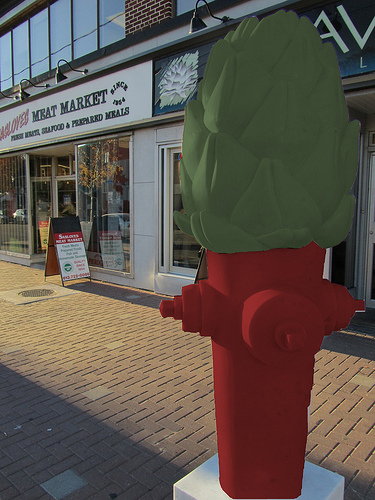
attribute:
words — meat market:
[31, 86, 108, 124]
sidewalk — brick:
[0, 259, 374, 499]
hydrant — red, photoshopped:
[157, 6, 365, 500]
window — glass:
[157, 142, 204, 279]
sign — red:
[42, 213, 93, 290]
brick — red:
[124, 0, 177, 38]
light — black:
[53, 59, 91, 83]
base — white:
[171, 450, 346, 499]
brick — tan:
[327, 430, 361, 448]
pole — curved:
[57, 58, 84, 73]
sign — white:
[0, 60, 155, 155]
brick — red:
[157, 8, 180, 18]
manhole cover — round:
[18, 287, 56, 300]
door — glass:
[53, 177, 78, 220]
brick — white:
[347, 371, 374, 388]